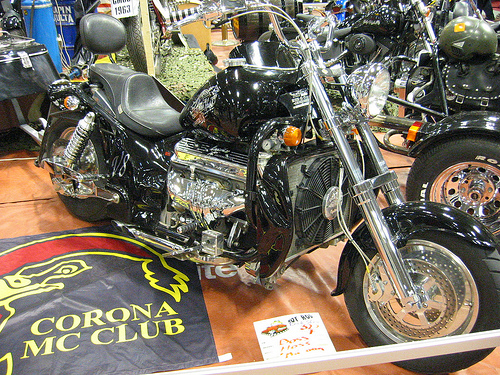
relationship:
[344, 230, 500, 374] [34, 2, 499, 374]
wheel on front of motorcycle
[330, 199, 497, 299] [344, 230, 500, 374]
fender on wheel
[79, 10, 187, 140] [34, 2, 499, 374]
seat on motorcycle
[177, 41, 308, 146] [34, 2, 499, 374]
gas tank on motorcycle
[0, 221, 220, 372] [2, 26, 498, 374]
flag on floor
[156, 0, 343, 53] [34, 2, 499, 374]
handlebars are on motorcycle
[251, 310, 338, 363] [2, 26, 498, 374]
paper on ground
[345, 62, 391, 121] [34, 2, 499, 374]
headlight on motorcycle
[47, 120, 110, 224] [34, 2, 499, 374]
wheel on back of motorcycle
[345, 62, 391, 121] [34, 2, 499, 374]
headlight on front of motorcycle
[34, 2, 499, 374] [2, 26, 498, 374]
motorcycle on floor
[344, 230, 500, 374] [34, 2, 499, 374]
wheel on motorcycle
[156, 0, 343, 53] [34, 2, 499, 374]
handlebars on motorcycle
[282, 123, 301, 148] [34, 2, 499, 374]
reflector on motorcycle